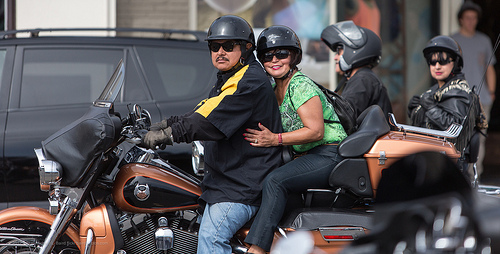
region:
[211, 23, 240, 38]
the helmet is black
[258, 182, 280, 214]
women wearing jeans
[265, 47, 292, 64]
sunglasses are black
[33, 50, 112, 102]
a window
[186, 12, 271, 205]
Man in a black and yellow shirt wearing a helmet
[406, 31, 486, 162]
Woman in leather jacket wearing a helmet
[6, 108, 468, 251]
Gold and black motorcycle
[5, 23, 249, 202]
Black car behind the man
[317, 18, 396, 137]
Man in a black jacket wearing a helmet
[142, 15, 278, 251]
Man in jeans wearing gloves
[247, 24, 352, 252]
Woman in sunglasses wearing jeans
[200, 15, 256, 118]
Man in sunglasses with a mustache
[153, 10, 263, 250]
this is a person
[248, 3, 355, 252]
this is a person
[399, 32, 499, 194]
this is a person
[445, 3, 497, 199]
this is a person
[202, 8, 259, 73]
this is a black helmet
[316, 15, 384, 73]
this is a black helmet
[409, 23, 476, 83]
this is a black helmet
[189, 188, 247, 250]
these are jeans pants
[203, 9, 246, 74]
Black helmet on head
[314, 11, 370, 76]
Black helmet on head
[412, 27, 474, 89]
Black helmet on head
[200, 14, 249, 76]
Person wearing black sunglasses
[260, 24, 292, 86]
Person wearing black sunglasses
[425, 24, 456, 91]
Person wearing black sunglasses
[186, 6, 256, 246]
Person on a motorcycle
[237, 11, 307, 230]
Person on a motorcycle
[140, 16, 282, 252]
man driving a motorbike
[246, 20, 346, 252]
passenger on a motorcycle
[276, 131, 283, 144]
pink bracelet on a woman's left arm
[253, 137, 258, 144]
wedding ring on a woman's hand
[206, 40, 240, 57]
sunglasses on a man's face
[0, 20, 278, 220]
black SUV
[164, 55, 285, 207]
man's black and yellow shirt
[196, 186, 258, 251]
man's blue jeans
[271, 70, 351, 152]
woman's green colored blouse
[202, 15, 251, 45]
helmet on the man driving the bike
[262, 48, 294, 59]
woman wearing black sunglasses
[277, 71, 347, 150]
woman wearing a green shirt